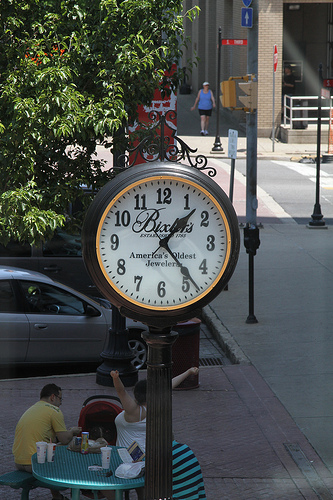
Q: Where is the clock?
A: On the street.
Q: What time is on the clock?
A: 1:24.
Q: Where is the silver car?
A: Parked by the sidewalk.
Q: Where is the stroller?
A: Next to the table.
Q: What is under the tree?
A: Cars.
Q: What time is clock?
A: 1:25.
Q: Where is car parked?
A: Parking space.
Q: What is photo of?
A: Sidewalk scene.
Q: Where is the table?
A: Sidewalk.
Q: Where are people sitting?
A: Around table.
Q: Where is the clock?
A: On the sidewalk.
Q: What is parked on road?
A: Silver car.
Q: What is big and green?
A: Tree.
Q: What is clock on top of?
A: Metal pole.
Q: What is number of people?
A: Three.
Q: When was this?
A: Daytime.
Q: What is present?
A: A clock.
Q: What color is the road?
A: Grey.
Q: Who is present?
A: People.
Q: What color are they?
A: White.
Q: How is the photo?
A: Clear.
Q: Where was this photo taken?
A: Near clock.